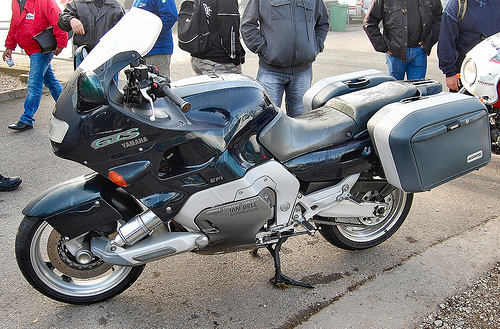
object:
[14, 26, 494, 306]
motorcycle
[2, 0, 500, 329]
area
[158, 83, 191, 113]
handle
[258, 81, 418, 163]
seat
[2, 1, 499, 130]
people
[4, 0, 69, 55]
jacket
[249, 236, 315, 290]
kickstand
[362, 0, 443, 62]
jacket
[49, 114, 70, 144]
light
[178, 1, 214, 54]
backpack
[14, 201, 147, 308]
wheel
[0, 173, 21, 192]
shoe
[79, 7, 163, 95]
windshield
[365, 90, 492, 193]
bag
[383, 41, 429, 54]
hands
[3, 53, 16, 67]
can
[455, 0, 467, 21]
stripes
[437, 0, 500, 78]
jacket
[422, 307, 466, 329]
gravel